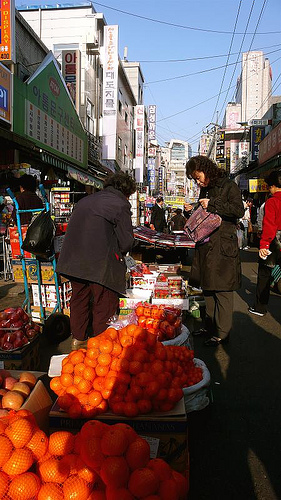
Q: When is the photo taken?
A: During the day.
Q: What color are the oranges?
A: Orange.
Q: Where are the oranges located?
A: In bins.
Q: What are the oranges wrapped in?
A: Net.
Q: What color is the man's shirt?
A: Red.